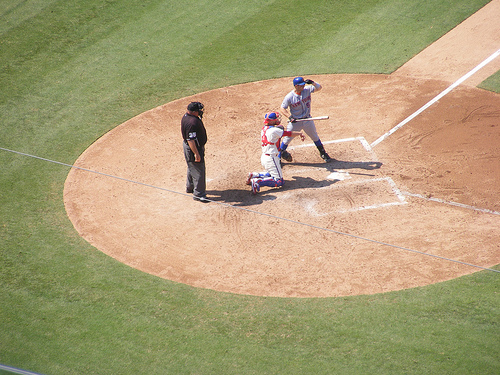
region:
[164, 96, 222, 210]
an umpire at a baseball game.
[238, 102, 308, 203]
a catcher at a baseball game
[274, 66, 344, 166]
a batter at a baseball game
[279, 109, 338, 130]
a player holding a bat at a baseball game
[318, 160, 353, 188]
home plate on a baseball diamond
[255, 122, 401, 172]
the batters box on a baseball diamond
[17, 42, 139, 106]
grass on a baseball field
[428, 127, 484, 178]
dirt on a baseball diamond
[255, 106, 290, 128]
catchers helmet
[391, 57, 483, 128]
baseline on a baseball diamond.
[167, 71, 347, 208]
Three baseball players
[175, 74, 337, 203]
An umpire, a catcher, and a swinger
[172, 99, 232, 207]
An umpire dressed in black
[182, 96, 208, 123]
The helmet of an umpire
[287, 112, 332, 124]
A baseball bat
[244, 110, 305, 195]
A baseball catcher kneeling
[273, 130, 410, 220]
Home base on a baseball field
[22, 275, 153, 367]
A neatly mowed patch of grass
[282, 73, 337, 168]
A baseball player holding a bat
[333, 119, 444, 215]
White markings on a baseball field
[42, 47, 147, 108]
Green grass behind the dirt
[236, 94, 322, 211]
Catcher is throwing the ball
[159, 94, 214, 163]
Umpire wearing black shirt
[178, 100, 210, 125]
Umpire wearing black mask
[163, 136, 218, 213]
Umpire wearing gray pants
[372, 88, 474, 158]
White lines on the baseball field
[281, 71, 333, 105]
Batter wearing blue helmet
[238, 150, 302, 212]
Catcher wearing blue knee pads and shin pads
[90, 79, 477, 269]
Home plate in a circle of brown dirt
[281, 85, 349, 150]
Man holding wooden bat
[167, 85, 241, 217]
Umpire watching the play.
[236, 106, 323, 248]
Catcher throwing the ball back to pitcher.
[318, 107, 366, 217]
Home plate.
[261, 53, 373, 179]
Batter getting ready to hit the ball.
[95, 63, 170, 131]
Green grass on the ball field.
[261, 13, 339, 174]
Batter has a blue helmet.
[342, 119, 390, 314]
White chalk lines on the ball field.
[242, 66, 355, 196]
Batter with batting gloves on his hands.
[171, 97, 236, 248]
Umpire with a face mask on.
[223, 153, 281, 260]
Dirt on the ball field.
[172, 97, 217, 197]
The home plate umpire.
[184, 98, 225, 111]
The umpire's protective mask.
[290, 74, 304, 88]
A blue batting helmet.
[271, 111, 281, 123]
A red catcher's mask.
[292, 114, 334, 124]
A wooden baseball bat.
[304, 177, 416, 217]
A smudged batter's box.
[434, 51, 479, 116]
A section of the third base line.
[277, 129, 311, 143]
The catcher's extended right arm.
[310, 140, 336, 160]
The batter's black shoe and blue sock.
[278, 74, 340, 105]
The batter adjusting his helmet.